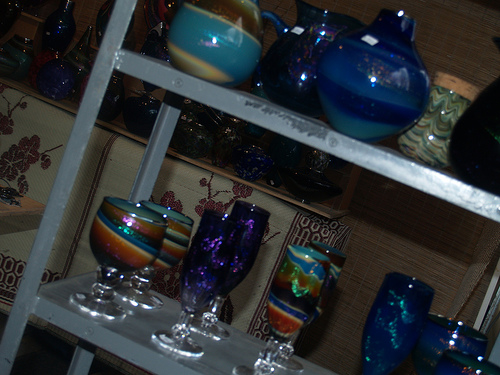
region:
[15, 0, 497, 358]
Metal shelving unit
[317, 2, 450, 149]
Blue glass vase sitting on the shelf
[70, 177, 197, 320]
Two multi-colored wine goblets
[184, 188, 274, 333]
Two blue champagne glasses on the shelf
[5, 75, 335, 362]
Tapestry in the background with flowers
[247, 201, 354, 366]
Two multicolored champagne glasses for sale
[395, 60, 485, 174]
Multicolored glass with a cork lid on it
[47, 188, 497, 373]
Eight beautiful glasses sitting on a shelf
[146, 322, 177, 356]
Sticker with the price of the glass on it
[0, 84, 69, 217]
Flowers woven into a rug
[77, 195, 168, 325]
Multicolored glass sitting on a shelf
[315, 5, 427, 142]
Dark blue and light blue glass decoration sitting on a shelf.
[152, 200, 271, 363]
Two purple colored tall glasses sitting on a shelf.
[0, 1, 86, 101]
Three smaller glasses sitting on a shelf.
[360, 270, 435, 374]
Tall skinny bright blue shiny glasses.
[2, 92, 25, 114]
Little sticks on the wallpaper.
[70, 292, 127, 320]
Bottom clear round base of glass.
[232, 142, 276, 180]
Shiny blue small glass on shelf.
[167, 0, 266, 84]
Tan blue and brown glass decoration on shelf.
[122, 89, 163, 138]
Small dark glass decoration on shelf.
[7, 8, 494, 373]
Interior shot, weather and time not distinguishable.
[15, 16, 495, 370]
Indoor, display area with dark lighting.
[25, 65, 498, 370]
Grey metal shelving in open style case.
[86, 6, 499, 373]
Multicolored glass works displayed.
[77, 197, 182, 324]
Colorful, striped goblets.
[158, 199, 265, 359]
Purple, glass stemware.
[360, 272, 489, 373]
Blue glass and goblet.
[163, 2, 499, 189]
Rounded, pottery-style glass containers and vases, in striped colors.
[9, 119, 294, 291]
Mural, or picture, backing shelves.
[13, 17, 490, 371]
Shelving shows photo taken at askew angle.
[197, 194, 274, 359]
blue sparkly wine glass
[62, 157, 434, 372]
grey shelf full of stemware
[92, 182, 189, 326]
two multi colored goblets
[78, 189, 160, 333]
a striped goblet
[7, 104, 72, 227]
floral fabric in the background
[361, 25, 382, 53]
white price tag on a vase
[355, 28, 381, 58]
price tag n a blue shiny vase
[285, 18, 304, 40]
price tag on a blue pitcher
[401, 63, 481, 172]
swirly glass jar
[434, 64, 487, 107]
cork topper to a glass jar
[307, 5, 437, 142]
a blown glass vase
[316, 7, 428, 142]
a blue vase of glass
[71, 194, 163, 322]
a multi color glass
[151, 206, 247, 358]
a blue crystal glass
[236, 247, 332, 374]
a skinny colored glass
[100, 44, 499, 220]
the top shelf visible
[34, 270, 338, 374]
the second visible shelf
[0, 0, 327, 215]
more glass behind the shelving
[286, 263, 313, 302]
a small design on the glass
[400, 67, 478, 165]
a light colored vase